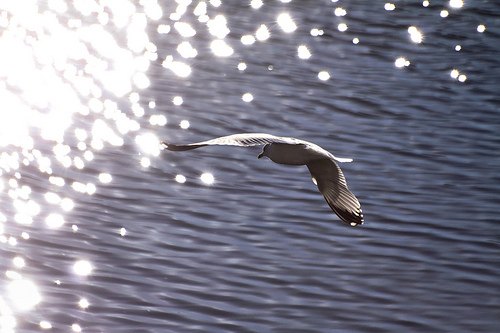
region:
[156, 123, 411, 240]
white bird flying through air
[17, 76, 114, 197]
sun shining on the water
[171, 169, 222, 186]
two sun spots on the water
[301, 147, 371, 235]
wing with black edging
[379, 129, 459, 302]
ripples and waves in the water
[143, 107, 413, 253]
bird with white wings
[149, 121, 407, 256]
bird soaring through the sky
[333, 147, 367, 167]
white tail feathers of bird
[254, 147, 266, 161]
tiny beak of a bird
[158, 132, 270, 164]
splayed feathers of a bird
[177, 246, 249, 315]
The water is visible.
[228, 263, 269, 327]
The water is visible.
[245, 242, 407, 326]
The water is visible.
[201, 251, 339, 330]
The water is visible.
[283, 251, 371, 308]
The water is visible.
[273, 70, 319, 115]
part of a water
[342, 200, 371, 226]
edge of a wing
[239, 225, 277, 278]
part of some waves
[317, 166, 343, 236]
edge of a wing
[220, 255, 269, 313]
part of a water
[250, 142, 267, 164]
part of a beak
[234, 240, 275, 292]
part of a water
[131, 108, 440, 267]
Seagull flying over water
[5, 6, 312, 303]
light reflected on water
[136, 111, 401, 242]
Seagull is white and brown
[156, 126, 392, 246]
Seagull has small beak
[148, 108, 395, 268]
Seagulls wings are open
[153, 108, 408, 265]
Wings are white and brown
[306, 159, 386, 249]
Brown tip on white wing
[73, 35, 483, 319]
water has many ripples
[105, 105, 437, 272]
seagull soars over water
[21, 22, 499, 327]
Water is dark blue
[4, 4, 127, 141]
reflection of bright light on the water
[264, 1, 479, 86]
specks of white light on the water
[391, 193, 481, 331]
rippled blue ocean water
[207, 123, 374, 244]
a flying grey bird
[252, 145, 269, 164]
the black beak of a flying bird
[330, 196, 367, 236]
the black tip of a bird's wing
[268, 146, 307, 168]
the underside of a bird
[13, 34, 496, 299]
a bird flying over the ocean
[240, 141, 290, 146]
black feathers along the backside of a bird's wing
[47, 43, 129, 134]
the sun's reflection in the water